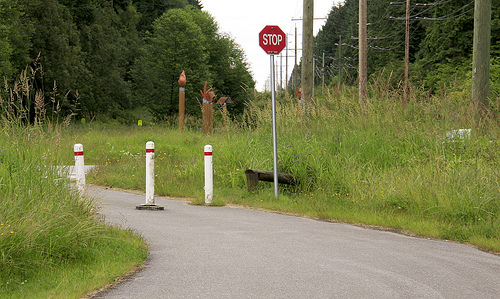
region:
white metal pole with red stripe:
[75, 145, 85, 197]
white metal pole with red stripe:
[143, 143, 152, 205]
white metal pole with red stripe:
[202, 145, 214, 200]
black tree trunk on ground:
[244, 169, 286, 188]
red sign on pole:
[257, 25, 283, 53]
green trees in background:
[0, 5, 248, 119]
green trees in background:
[297, 0, 498, 80]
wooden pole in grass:
[303, 5, 313, 117]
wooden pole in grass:
[471, 2, 498, 117]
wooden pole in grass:
[361, 3, 366, 105]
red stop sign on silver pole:
[253, 20, 291, 196]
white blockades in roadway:
[66, 139, 223, 214]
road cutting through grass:
[74, 179, 499, 287]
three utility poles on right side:
[295, 8, 498, 128]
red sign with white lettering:
[257, 20, 291, 57]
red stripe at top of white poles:
[75, 148, 217, 158]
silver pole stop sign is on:
[265, 53, 285, 201]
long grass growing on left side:
[2, 58, 97, 269]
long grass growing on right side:
[222, 76, 485, 217]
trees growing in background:
[12, 11, 481, 131]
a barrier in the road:
[58, 133, 239, 222]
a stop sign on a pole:
[253, 18, 289, 197]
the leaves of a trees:
[14, 17, 78, 55]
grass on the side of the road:
[13, 182, 104, 257]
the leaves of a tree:
[158, 27, 195, 57]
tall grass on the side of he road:
[320, 97, 353, 150]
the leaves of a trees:
[427, 20, 458, 50]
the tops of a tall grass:
[0, 57, 60, 125]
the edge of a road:
[230, 197, 316, 217]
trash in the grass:
[436, 115, 482, 150]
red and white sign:
[252, 23, 293, 58]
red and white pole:
[66, 136, 92, 203]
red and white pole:
[132, 135, 161, 215]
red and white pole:
[195, 137, 225, 208]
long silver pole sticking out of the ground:
[267, 53, 283, 200]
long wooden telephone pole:
[296, 1, 318, 122]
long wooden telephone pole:
[353, 2, 370, 112]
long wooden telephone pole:
[400, 2, 417, 107]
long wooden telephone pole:
[470, 2, 493, 130]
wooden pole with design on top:
[175, 68, 192, 136]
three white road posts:
[71, 125, 228, 225]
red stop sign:
[245, 20, 302, 202]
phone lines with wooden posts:
[271, 0, 498, 152]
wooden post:
[464, 0, 499, 128]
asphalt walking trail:
[29, 132, 489, 294]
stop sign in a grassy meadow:
[241, 13, 308, 208]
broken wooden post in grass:
[237, 160, 302, 202]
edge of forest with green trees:
[4, 0, 254, 130]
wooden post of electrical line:
[299, 3, 321, 128]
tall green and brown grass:
[6, 65, 143, 296]